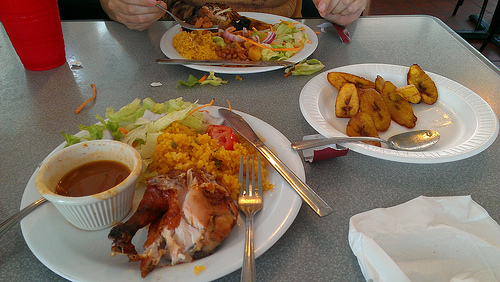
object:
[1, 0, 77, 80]
cup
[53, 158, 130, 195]
gravy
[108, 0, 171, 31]
hand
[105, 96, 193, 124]
lettuce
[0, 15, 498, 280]
table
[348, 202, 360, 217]
ground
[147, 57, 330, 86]
lettuce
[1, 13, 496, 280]
table top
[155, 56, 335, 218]
knives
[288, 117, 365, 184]
paper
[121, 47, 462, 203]
plantains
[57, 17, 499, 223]
plate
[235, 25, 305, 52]
carrot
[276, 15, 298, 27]
carrot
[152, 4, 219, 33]
fork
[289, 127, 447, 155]
spoon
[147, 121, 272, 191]
rice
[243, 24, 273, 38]
onion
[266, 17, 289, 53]
lettuce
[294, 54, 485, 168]
plate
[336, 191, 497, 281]
paper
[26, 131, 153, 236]
bowl